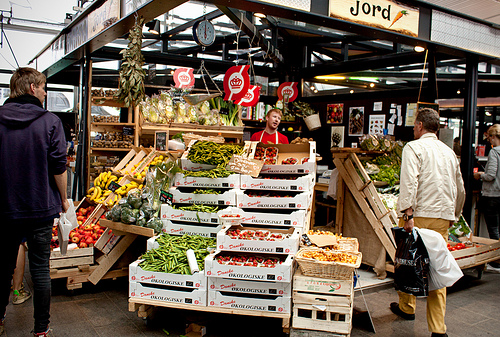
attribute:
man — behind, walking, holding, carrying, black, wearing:
[358, 98, 474, 304]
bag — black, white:
[389, 210, 432, 298]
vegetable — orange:
[318, 222, 364, 262]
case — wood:
[209, 234, 304, 266]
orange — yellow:
[192, 99, 215, 118]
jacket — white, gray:
[402, 140, 472, 213]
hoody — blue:
[3, 94, 63, 136]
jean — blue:
[2, 217, 81, 310]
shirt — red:
[245, 128, 321, 158]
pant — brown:
[416, 222, 467, 246]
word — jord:
[312, 4, 400, 40]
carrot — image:
[366, 4, 436, 41]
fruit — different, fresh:
[98, 142, 328, 306]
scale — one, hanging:
[166, 8, 230, 119]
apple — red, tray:
[58, 186, 134, 266]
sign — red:
[206, 51, 267, 110]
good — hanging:
[81, 12, 170, 147]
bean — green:
[166, 229, 218, 280]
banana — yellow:
[70, 159, 145, 210]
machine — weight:
[166, 37, 244, 108]